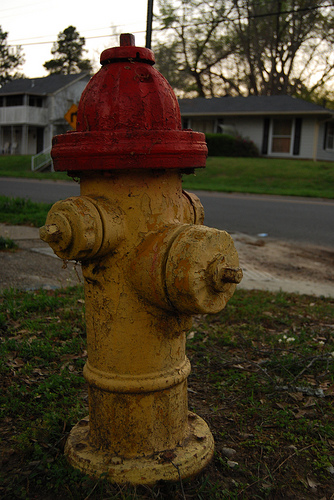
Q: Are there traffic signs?
A: Yes, there is a traffic sign.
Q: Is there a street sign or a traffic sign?
A: Yes, there is a traffic sign.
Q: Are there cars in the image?
A: No, there are no cars.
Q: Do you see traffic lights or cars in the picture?
A: No, there are no cars or traffic lights.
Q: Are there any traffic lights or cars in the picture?
A: No, there are no cars or traffic lights.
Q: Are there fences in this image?
A: No, there are no fences.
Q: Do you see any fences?
A: No, there are no fences.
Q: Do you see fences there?
A: No, there are no fences.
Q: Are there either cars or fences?
A: No, there are no fences or cars.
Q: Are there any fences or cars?
A: No, there are no fences or cars.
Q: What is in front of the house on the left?
A: The porch is in front of the house.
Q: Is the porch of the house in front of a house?
A: Yes, the porch is in front of a house.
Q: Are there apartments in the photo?
A: No, there are no apartments.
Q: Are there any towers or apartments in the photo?
A: No, there are no apartments or towers.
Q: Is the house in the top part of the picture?
A: Yes, the house is in the top of the image.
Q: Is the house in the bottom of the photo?
A: No, the house is in the top of the image.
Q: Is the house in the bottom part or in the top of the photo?
A: The house is in the top of the image.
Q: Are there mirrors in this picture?
A: No, there are no mirrors.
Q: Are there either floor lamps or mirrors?
A: No, there are no mirrors or floor lamps.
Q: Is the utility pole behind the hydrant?
A: Yes, the utility pole is behind the hydrant.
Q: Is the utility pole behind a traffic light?
A: No, the utility pole is behind the hydrant.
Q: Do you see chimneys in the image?
A: No, there are no chimneys.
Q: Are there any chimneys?
A: No, there are no chimneys.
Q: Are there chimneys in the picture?
A: No, there are no chimneys.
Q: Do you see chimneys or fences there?
A: No, there are no chimneys or fences.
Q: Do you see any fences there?
A: No, there are no fences.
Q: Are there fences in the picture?
A: No, there are no fences.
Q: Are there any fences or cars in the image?
A: No, there are no fences or cars.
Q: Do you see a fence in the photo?
A: No, there are no fences.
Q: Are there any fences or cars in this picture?
A: No, there are no fences or cars.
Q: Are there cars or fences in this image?
A: No, there are no fences or cars.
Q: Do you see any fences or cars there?
A: No, there are no fences or cars.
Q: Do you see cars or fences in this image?
A: No, there are no fences or cars.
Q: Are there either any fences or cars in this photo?
A: No, there are no cars or fences.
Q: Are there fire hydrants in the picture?
A: Yes, there is a fire hydrant.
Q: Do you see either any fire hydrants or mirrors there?
A: Yes, there is a fire hydrant.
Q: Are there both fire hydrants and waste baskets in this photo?
A: No, there is a fire hydrant but no waste baskets.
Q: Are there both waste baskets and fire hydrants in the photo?
A: No, there is a fire hydrant but no waste baskets.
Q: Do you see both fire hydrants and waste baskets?
A: No, there is a fire hydrant but no waste baskets.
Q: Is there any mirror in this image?
A: No, there are no mirrors.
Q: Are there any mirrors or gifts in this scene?
A: No, there are no mirrors or gifts.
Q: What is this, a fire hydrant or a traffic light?
A: This is a fire hydrant.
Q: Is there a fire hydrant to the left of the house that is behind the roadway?
A: Yes, there is a fire hydrant to the left of the house.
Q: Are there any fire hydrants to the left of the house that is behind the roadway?
A: Yes, there is a fire hydrant to the left of the house.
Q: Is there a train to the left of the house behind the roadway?
A: No, there is a fire hydrant to the left of the house.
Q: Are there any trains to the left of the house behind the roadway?
A: No, there is a fire hydrant to the left of the house.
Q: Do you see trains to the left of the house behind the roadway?
A: No, there is a fire hydrant to the left of the house.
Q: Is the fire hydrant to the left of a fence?
A: No, the fire hydrant is to the left of the house.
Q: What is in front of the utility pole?
A: The hydrant is in front of the utility pole.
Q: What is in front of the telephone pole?
A: The hydrant is in front of the utility pole.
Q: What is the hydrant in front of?
A: The hydrant is in front of the telephone pole.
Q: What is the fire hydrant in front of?
A: The hydrant is in front of the telephone pole.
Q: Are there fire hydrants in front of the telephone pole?
A: Yes, there is a fire hydrant in front of the telephone pole.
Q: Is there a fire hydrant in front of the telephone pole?
A: Yes, there is a fire hydrant in front of the telephone pole.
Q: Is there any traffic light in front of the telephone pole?
A: No, there is a fire hydrant in front of the telephone pole.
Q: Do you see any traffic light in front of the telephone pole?
A: No, there is a fire hydrant in front of the telephone pole.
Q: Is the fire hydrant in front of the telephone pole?
A: Yes, the fire hydrant is in front of the telephone pole.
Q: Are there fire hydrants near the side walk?
A: Yes, there is a fire hydrant near the side walk.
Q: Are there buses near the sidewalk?
A: No, there is a fire hydrant near the sidewalk.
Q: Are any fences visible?
A: No, there are no fences.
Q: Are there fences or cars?
A: No, there are no fences or cars.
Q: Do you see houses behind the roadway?
A: Yes, there is a house behind the roadway.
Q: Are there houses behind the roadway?
A: Yes, there is a house behind the roadway.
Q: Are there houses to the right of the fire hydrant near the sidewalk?
A: Yes, there is a house to the right of the hydrant.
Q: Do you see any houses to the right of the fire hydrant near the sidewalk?
A: Yes, there is a house to the right of the hydrant.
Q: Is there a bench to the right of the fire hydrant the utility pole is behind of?
A: No, there is a house to the right of the hydrant.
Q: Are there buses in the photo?
A: No, there are no buses.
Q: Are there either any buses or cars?
A: No, there are no buses or cars.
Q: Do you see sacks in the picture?
A: No, there are no sacks.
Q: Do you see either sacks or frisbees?
A: No, there are no sacks or frisbees.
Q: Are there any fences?
A: No, there are no fences.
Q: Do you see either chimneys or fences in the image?
A: No, there are no fences or chimneys.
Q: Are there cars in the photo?
A: No, there are no cars.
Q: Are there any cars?
A: No, there are no cars.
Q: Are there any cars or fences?
A: No, there are no cars or fences.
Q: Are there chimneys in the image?
A: No, there are no chimneys.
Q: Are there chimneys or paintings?
A: No, there are no chimneys or paintings.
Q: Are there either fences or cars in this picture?
A: No, there are no cars or fences.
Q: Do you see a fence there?
A: No, there are no fences.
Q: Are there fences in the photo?
A: No, there are no fences.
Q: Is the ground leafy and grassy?
A: Yes, the ground is leafy and grassy.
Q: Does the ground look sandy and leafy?
A: No, the ground is leafy but grassy.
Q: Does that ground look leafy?
A: Yes, the ground is leafy.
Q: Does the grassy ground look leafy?
A: Yes, the ground is leafy.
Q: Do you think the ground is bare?
A: No, the ground is leafy.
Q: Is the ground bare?
A: No, the ground is leafy.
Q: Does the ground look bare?
A: No, the ground is leafy.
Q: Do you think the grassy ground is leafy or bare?
A: The ground is leafy.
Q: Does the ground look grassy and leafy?
A: Yes, the ground is grassy and leafy.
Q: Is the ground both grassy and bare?
A: No, the ground is grassy but leafy.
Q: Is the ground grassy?
A: Yes, the ground is grassy.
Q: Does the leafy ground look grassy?
A: Yes, the ground is grassy.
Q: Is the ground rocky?
A: No, the ground is grassy.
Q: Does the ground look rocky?
A: No, the ground is grassy.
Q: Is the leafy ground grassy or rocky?
A: The ground is grassy.